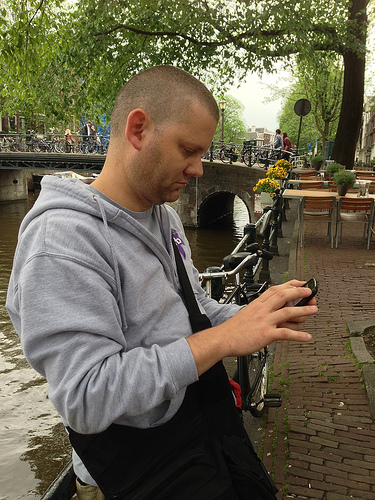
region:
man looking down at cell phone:
[35, 53, 282, 398]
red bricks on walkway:
[318, 268, 359, 410]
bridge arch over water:
[194, 181, 257, 239]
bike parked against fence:
[212, 228, 278, 403]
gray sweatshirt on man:
[14, 171, 187, 424]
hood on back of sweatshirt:
[26, 170, 93, 223]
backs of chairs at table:
[292, 189, 370, 246]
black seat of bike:
[220, 245, 260, 274]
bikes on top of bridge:
[18, 122, 97, 155]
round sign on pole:
[291, 93, 316, 127]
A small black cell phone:
[277, 271, 326, 320]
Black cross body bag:
[61, 228, 271, 495]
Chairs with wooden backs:
[291, 197, 372, 259]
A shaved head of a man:
[107, 59, 223, 209]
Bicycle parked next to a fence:
[206, 244, 294, 425]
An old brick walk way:
[285, 350, 370, 497]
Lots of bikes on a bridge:
[0, 116, 105, 157]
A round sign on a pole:
[289, 93, 317, 162]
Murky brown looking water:
[2, 403, 49, 483]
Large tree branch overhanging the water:
[65, 6, 347, 64]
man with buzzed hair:
[29, 33, 263, 248]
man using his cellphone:
[15, 73, 334, 460]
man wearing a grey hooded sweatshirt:
[11, 86, 343, 442]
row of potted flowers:
[247, 131, 301, 219]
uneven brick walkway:
[261, 205, 371, 472]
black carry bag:
[19, 172, 287, 498]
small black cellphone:
[257, 256, 326, 323]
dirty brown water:
[0, 159, 267, 486]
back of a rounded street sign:
[279, 87, 326, 164]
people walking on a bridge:
[25, 93, 312, 210]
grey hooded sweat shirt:
[18, 176, 218, 480]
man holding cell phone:
[17, 66, 319, 495]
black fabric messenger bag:
[54, 350, 280, 499]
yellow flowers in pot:
[254, 176, 280, 207]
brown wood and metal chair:
[298, 194, 338, 249]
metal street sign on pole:
[290, 97, 312, 159]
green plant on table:
[331, 169, 355, 199]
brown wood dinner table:
[283, 184, 374, 219]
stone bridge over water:
[3, 150, 277, 231]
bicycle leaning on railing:
[222, 140, 257, 167]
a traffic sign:
[269, 73, 337, 176]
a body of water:
[0, 53, 250, 492]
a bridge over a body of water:
[8, 110, 337, 235]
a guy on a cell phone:
[105, 76, 333, 339]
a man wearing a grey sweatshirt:
[9, 45, 240, 459]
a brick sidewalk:
[271, 216, 367, 491]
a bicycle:
[202, 260, 289, 406]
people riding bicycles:
[10, 101, 229, 190]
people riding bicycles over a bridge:
[4, 84, 316, 198]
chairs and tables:
[263, 144, 374, 245]